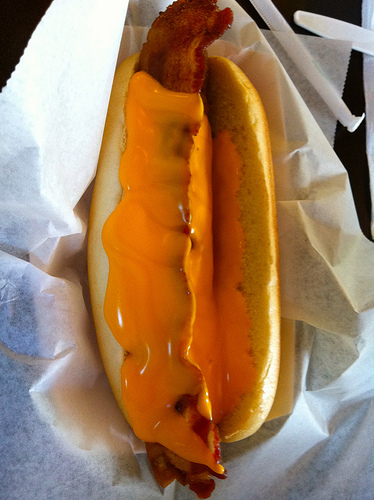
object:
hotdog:
[99, 0, 236, 500]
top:
[82, 0, 278, 500]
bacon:
[132, 0, 237, 96]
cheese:
[134, 113, 244, 345]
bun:
[206, 54, 281, 446]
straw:
[256, 8, 345, 81]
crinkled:
[284, 122, 344, 271]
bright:
[123, 113, 208, 359]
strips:
[120, 68, 242, 213]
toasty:
[86, 0, 280, 499]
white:
[277, 116, 352, 231]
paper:
[267, 76, 322, 155]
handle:
[291, 9, 374, 56]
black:
[335, 109, 373, 231]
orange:
[134, 116, 187, 255]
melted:
[140, 158, 245, 262]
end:
[138, 36, 219, 89]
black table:
[0, 0, 374, 499]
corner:
[273, 12, 369, 119]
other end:
[133, 17, 251, 85]